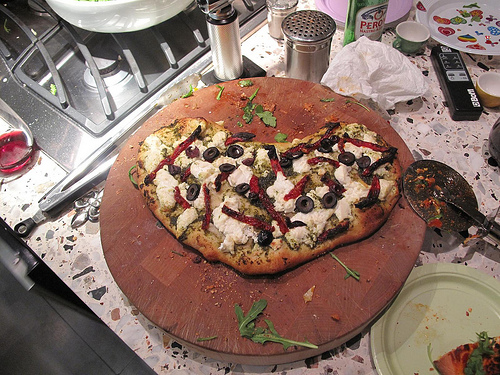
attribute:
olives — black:
[201, 141, 243, 173]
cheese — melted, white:
[264, 170, 294, 211]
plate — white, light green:
[367, 262, 498, 374]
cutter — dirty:
[394, 152, 499, 249]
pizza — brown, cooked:
[130, 106, 410, 282]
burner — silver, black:
[2, 2, 264, 135]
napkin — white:
[318, 32, 434, 111]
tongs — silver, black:
[33, 97, 170, 214]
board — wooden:
[91, 73, 436, 371]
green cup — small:
[390, 20, 432, 62]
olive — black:
[234, 175, 260, 205]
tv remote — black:
[426, 43, 484, 126]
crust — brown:
[349, 210, 389, 241]